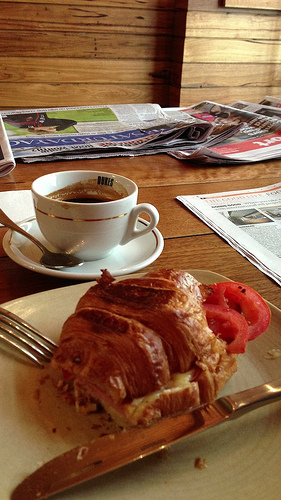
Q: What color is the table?
A: Brown.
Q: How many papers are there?
A: Three.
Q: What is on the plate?
A: Sandwich.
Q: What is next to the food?
A: Coffee.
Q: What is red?
A: Tomatoes.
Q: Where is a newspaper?
A: On the table.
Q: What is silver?
A: Utensils.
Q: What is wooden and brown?
A: Table.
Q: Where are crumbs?
A: On a plate.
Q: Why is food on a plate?
A: To be eaten.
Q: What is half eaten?
A: Croissant.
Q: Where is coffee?
A: In a cup.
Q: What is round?
A: Small plate.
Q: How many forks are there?
A: One.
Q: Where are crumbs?
A: On a plate.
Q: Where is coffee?
A: In a cup.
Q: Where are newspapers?
A: On the table.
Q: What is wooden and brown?
A: Table.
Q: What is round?
A: Coffee cup.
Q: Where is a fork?
A: On plate.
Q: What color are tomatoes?
A: Red.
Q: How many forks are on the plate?
A: One.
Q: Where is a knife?
A: On the plate.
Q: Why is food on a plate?
A: To be eaten.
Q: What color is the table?
A: Brown.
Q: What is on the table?
A: A sandwich.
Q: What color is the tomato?
A: Red.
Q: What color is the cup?
A: White.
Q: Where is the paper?
A: On the table.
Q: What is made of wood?
A: The wall.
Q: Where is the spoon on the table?
A: In the saucer.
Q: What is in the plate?
A: A sandwich.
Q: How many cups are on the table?
A: One.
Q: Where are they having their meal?
A: At the table.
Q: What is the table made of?
A: Wood.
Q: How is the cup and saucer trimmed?
A: In gold.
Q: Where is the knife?
A: In the plate.